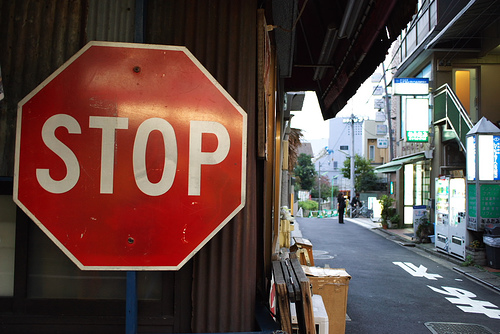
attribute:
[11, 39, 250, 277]
sign — stop sign, red, white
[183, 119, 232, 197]
p — white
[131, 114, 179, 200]
o — white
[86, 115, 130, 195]
t — white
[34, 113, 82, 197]
s — white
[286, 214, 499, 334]
pavement — black, without cars, gray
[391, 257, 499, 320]
writing — white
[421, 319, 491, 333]
cover — silver, iron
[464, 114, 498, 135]
pyramid — grey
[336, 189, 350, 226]
person — standing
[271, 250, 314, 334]
wood — beside building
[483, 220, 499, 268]
trash can — black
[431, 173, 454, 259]
vending machine — one of two, white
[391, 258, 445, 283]
symbol — white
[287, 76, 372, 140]
sky — cloudy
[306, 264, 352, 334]
box — brown, cardboard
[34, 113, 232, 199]
letters — white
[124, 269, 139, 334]
pole — blue, metal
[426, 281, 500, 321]
marking — white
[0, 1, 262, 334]
wall — metal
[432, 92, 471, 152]
stairs — green